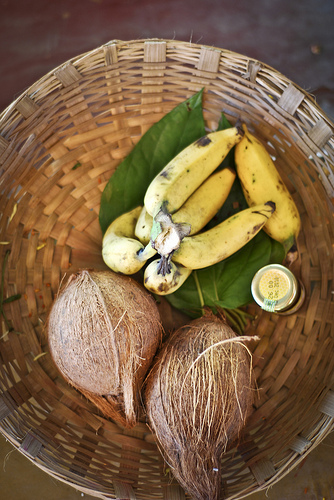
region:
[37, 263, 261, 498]
two coconuts, no lime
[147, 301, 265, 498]
coconut @ right is extremely hairy + inexplicably long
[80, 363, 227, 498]
tops of coconuts are uncut & left extended for some reason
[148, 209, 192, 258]
top of banana bunch is off-white+off-grey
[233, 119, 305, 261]
lone banana, short+stout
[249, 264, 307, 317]
small round jar of something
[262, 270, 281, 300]
26.00+Dec on small round jar; year is indecipherable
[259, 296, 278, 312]
green+white sticker on small round jar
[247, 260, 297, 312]
gold cap w/ buttercup yellow centre on small round jar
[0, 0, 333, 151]
table @ top is dusty red+grey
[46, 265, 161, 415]
Coconut with husk in a basket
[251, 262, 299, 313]
Bottle cap in a basket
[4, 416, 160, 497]
Side of a round brown wicker basket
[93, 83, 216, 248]
Green banana leaf in a basket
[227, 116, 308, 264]
Single banana in a basket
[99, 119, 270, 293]
Bunch of bananas in a basket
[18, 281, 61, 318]
Orange flecks behind a basket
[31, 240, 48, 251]
Yellow fleck in a basket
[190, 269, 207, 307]
Leaf stem of a banana leaf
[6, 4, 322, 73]
Table under a basket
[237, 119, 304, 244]
a ripe banana in a basket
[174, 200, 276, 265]
a ripe banana in a basket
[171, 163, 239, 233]
a ripe banana in a basket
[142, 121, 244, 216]
a ripe banana in a basket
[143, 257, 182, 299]
a ripe banana in a basket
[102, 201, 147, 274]
a ripe banana in a basket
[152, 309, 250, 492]
a coconut in a basket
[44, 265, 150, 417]
a coconut in a basket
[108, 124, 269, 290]
a bunch of bananas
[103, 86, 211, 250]
a green leaf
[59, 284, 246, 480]
two coconuts in basket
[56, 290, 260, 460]
the coconuts are hairy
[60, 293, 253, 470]
the coconuts are brown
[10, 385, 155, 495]
the basket is woven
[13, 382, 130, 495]
the basket is brown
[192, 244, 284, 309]
the leaves are green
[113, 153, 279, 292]
leaves are below banana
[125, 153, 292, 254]
the bananas are yellow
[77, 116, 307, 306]
bananas are in basket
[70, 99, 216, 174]
leaves are in basket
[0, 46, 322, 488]
basket filled with fruit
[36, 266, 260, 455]
two hairy coconuts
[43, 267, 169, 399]
round hairy coconut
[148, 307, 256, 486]
oblong shaped hairy coconut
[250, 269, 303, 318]
small glass jar in a basket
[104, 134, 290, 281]
bunch of bananas on green leaves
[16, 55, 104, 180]
woven wicker basket with fruit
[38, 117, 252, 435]
bananas and coconuts in a basket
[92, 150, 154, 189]
green leaves underneath a bunch of bananas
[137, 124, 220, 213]
yellow banana with a brown spot